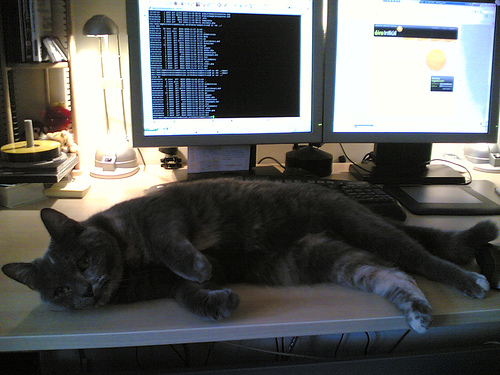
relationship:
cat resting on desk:
[2, 177, 498, 332] [5, 128, 498, 368]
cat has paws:
[0, 177, 499, 335] [196, 282, 247, 317]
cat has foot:
[0, 177, 499, 335] [406, 301, 435, 335]